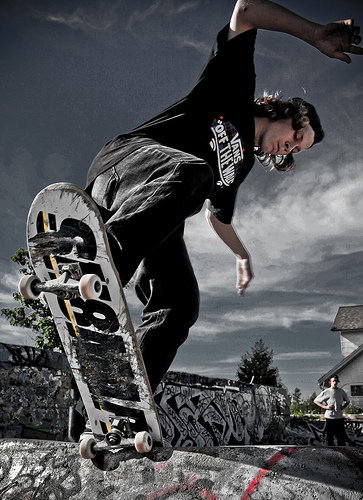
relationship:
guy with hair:
[82, 0, 363, 435] [255, 98, 312, 135]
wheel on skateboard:
[75, 273, 114, 309] [23, 199, 153, 462]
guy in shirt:
[313, 374, 350, 447] [324, 389, 342, 419]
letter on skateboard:
[60, 340, 130, 374] [23, 199, 153, 462]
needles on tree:
[249, 346, 273, 358] [237, 335, 296, 387]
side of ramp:
[8, 362, 280, 451] [15, 401, 361, 487]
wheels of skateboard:
[20, 251, 109, 294] [23, 199, 153, 462]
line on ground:
[247, 442, 283, 494] [23, 445, 339, 488]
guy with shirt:
[313, 374, 350, 447] [324, 389, 342, 419]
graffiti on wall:
[166, 382, 274, 439] [24, 340, 329, 446]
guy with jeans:
[313, 374, 350, 447] [324, 421, 358, 447]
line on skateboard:
[57, 287, 91, 350] [23, 199, 153, 462]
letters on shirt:
[213, 108, 241, 201] [101, 80, 272, 207]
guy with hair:
[137, 9, 299, 305] [255, 98, 312, 135]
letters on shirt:
[209, 120, 244, 188] [101, 80, 272, 207]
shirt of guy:
[101, 80, 272, 207] [82, 0, 363, 435]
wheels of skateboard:
[61, 415, 170, 469] [23, 199, 153, 462]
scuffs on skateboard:
[53, 320, 107, 370] [23, 199, 153, 462]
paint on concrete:
[256, 454, 298, 490] [86, 426, 336, 499]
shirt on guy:
[324, 389, 342, 419] [313, 374, 350, 447]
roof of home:
[328, 282, 362, 318] [319, 298, 357, 394]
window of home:
[349, 376, 362, 407] [316, 305, 358, 429]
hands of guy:
[319, 397, 342, 421] [313, 374, 350, 447]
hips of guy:
[324, 410, 348, 424] [313, 374, 350, 447]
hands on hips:
[319, 397, 342, 421] [324, 410, 348, 424]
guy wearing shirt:
[313, 374, 350, 447] [324, 389, 342, 419]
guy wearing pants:
[313, 374, 350, 447] [321, 416, 353, 449]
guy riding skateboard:
[82, 0, 363, 435] [23, 199, 153, 462]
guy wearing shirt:
[82, 0, 363, 435] [101, 80, 272, 207]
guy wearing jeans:
[82, 0, 363, 435] [98, 175, 187, 365]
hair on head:
[255, 98, 312, 135] [242, 89, 321, 166]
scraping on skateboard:
[66, 337, 137, 405] [23, 199, 153, 462]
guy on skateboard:
[137, 9, 299, 305] [23, 199, 153, 462]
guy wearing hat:
[137, 9, 299, 305] [292, 77, 321, 145]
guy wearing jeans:
[137, 9, 299, 305] [98, 175, 187, 365]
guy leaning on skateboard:
[137, 9, 299, 305] [23, 199, 153, 462]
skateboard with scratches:
[23, 199, 153, 462] [68, 330, 129, 397]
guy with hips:
[314, 372, 360, 446] [324, 410, 348, 424]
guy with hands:
[314, 372, 360, 446] [319, 397, 342, 421]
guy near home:
[314, 372, 360, 446] [316, 305, 358, 429]